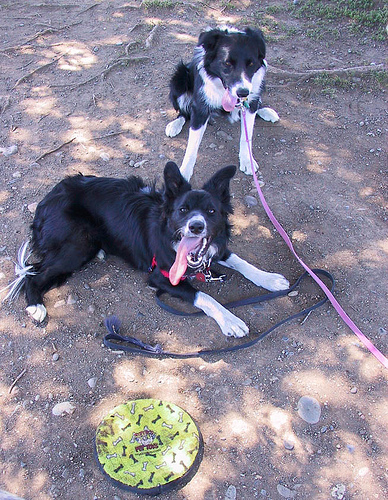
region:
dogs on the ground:
[28, 11, 387, 362]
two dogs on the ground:
[19, 6, 374, 336]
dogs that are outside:
[30, 11, 354, 362]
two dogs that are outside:
[14, 29, 382, 409]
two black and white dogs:
[30, 4, 385, 314]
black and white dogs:
[14, 11, 369, 365]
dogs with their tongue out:
[18, 6, 371, 362]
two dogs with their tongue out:
[16, 11, 371, 384]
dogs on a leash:
[29, 9, 349, 364]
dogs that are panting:
[9, 30, 380, 374]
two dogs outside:
[38, 27, 352, 380]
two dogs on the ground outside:
[1, 31, 367, 371]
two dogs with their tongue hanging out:
[17, 15, 385, 343]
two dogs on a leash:
[17, 20, 357, 393]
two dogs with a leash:
[28, 21, 363, 375]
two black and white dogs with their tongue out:
[14, 28, 382, 427]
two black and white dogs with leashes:
[23, 1, 382, 402]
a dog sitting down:
[136, 14, 346, 197]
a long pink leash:
[259, 189, 309, 257]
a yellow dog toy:
[84, 390, 211, 490]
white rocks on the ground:
[230, 390, 361, 499]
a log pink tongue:
[167, 238, 183, 292]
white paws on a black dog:
[198, 268, 294, 338]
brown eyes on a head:
[220, 54, 263, 71]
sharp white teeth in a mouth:
[194, 243, 207, 263]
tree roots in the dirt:
[107, 22, 162, 72]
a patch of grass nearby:
[306, 0, 376, 36]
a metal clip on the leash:
[206, 271, 224, 284]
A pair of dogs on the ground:
[1, 21, 288, 339]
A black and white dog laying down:
[0, 159, 291, 341]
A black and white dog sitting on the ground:
[165, 24, 278, 185]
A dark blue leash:
[98, 269, 335, 357]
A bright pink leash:
[244, 110, 387, 365]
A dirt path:
[1, 0, 386, 497]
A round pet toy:
[96, 398, 200, 487]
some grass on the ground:
[147, 1, 387, 91]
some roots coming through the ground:
[0, 4, 157, 159]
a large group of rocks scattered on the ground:
[1, 144, 384, 499]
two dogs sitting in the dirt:
[10, 9, 363, 364]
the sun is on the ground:
[193, 323, 373, 488]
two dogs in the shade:
[29, 4, 315, 376]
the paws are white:
[200, 238, 295, 353]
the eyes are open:
[170, 196, 227, 222]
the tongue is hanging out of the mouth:
[149, 232, 205, 283]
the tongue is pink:
[148, 228, 206, 281]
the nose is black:
[180, 213, 201, 229]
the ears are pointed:
[131, 144, 243, 209]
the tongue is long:
[140, 225, 227, 306]